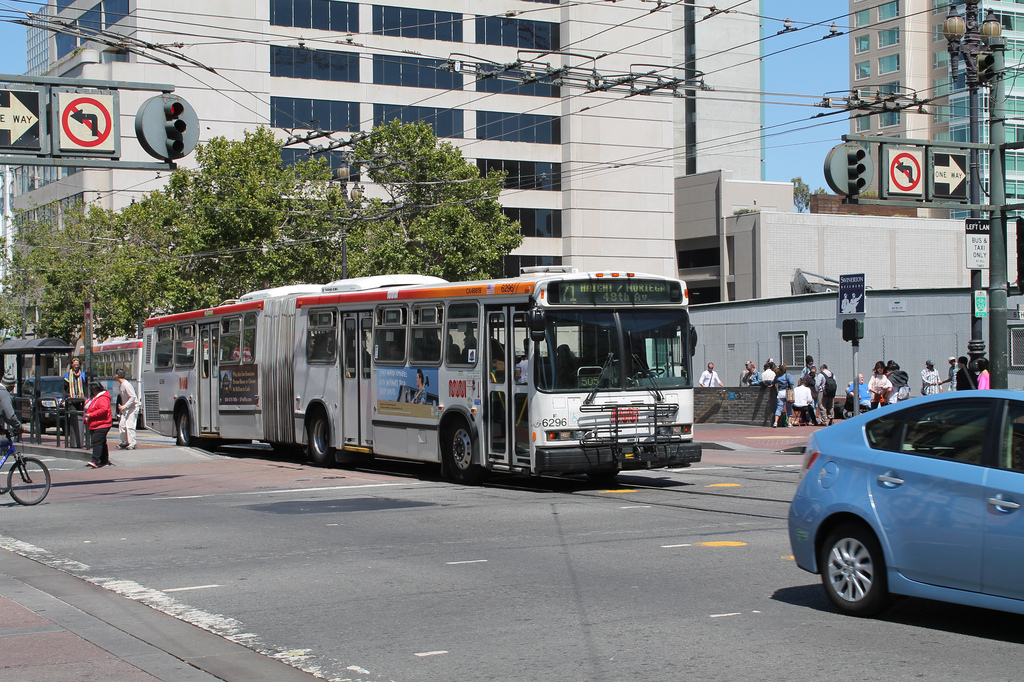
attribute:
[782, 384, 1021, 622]
car — blue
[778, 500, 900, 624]
tire — black, round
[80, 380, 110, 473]
person — paved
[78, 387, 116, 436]
coat — red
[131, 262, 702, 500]
bus — long, white